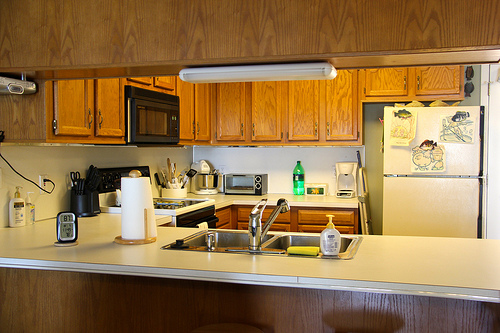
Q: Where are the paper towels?
A: To the left of the sink.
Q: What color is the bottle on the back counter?
A: Green.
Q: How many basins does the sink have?
A: Two.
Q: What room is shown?
A: Kitchen.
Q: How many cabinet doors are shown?
A: Twelve.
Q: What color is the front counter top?
A: Yellow.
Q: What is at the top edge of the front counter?
A: A metal strip.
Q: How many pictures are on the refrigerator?
A: Three.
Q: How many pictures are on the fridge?
A: 3.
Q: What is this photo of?
A: Kitchen.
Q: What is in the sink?
A: Nothing.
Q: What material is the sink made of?
A: Stainless Steel.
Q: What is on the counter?
A: Paper towels and a clock.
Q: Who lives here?
A: A family.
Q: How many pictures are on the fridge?
A: One.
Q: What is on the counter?
A: Paper towels.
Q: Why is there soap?
A: To wash your hands.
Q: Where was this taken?
A: In the kitchen.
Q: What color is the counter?
A: White.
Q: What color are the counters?
A: Brown.